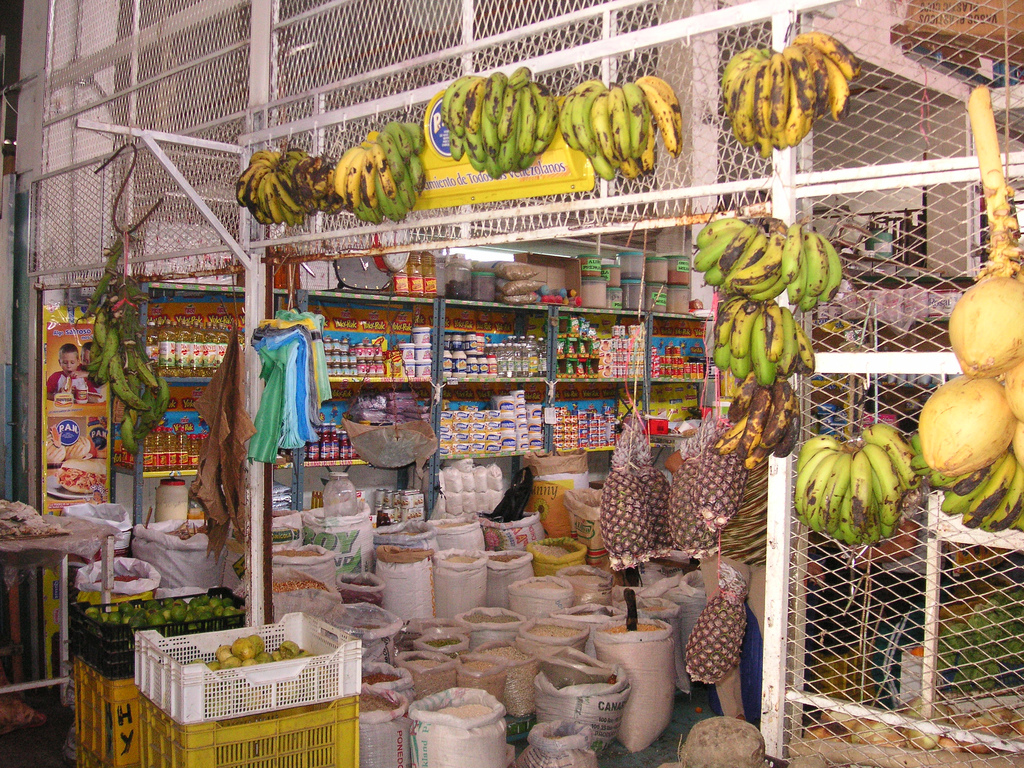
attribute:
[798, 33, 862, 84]
banana — yellow, brown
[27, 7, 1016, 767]
wall — white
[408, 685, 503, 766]
sack — white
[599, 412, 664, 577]
pineapple — fresh, hanging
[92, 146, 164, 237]
hook — large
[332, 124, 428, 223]
bananas — bunch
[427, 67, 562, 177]
bananas — bunch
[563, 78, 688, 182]
bananas — bunch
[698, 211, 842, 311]
bananas — bunch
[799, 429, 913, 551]
bananas — bunch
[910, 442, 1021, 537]
bananas — bunch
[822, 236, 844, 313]
banana — green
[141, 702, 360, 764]
crate — rectangular, yellow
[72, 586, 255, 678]
crate — black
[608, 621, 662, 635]
spice — yellow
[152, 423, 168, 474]
bottle — yellow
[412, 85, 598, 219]
sign — yellow